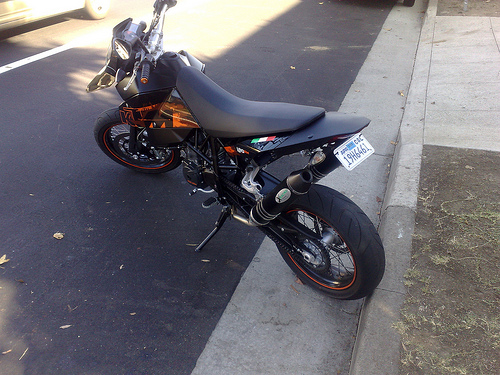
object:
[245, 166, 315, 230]
muffler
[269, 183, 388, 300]
back wheel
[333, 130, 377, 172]
license plate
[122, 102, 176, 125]
red strip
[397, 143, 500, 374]
dirt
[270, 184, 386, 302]
tire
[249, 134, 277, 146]
flag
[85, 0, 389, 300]
motorcycle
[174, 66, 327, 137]
seat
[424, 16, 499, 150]
ground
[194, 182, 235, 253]
kickstand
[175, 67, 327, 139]
black seat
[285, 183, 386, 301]
stripe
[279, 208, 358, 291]
rim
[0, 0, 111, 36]
car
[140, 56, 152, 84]
handlebar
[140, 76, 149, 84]
tip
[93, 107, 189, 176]
wheel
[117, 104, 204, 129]
orange design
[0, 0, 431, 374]
road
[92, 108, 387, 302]
tires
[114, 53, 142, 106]
clutch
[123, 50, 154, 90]
hand grip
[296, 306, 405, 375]
curb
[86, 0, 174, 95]
handlebars